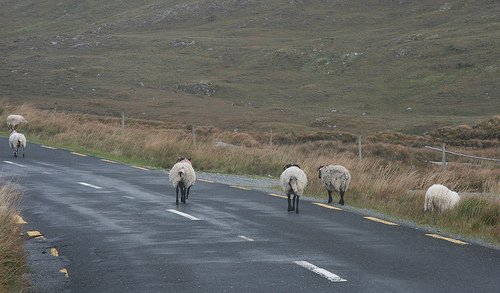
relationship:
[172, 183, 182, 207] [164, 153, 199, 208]
leg part of sheep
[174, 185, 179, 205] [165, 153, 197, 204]
leg of sheep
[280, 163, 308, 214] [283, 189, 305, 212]
sheep with black legs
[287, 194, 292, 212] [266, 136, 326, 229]
black leg of sheep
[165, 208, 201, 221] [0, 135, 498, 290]
line on road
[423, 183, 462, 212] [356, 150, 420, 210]
sheep on grass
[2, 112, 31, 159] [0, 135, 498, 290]
sheep on road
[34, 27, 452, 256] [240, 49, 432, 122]
field with grass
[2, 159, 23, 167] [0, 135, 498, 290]
white line on road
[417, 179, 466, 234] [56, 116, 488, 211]
sheep in grass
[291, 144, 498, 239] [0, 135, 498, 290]
tall grass beside road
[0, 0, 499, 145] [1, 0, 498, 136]
grass on hillside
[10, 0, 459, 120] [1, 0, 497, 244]
rocks on hillside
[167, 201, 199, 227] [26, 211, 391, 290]
line in road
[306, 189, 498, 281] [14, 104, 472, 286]
lines on road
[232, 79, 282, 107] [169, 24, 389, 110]
grass on hill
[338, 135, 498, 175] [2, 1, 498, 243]
gate road on grass